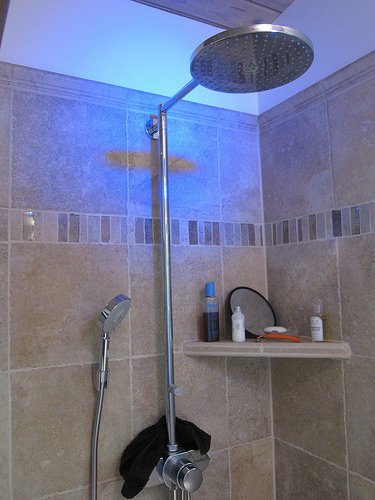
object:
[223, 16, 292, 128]
corner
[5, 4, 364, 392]
shower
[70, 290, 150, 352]
small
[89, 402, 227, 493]
washcloth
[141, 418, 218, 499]
handle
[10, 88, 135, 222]
brown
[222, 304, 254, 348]
soap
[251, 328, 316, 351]
razor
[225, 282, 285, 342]
mirror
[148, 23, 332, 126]
large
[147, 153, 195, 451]
pipes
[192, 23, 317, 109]
head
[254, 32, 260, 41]
holes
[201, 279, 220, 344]
bottle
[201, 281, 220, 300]
top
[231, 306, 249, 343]
bottle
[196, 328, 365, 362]
shelf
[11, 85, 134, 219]
tile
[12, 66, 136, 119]
tile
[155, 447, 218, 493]
knob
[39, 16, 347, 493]
water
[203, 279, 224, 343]
shampoo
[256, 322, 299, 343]
dish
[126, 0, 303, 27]
light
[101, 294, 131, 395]
shower head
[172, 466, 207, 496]
button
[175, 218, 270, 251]
tiles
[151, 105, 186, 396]
long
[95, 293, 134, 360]
shower head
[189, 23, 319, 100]
shower head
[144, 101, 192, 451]
piping